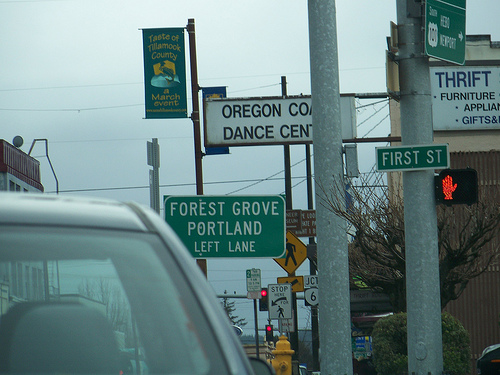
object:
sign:
[376, 144, 450, 173]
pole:
[396, 0, 444, 374]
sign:
[436, 170, 479, 203]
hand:
[443, 175, 457, 200]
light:
[261, 291, 267, 296]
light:
[266, 326, 271, 331]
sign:
[162, 194, 287, 260]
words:
[171, 201, 226, 216]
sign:
[207, 98, 311, 141]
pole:
[205, 136, 311, 149]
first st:
[381, 150, 443, 166]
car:
[0, 191, 248, 373]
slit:
[123, 202, 158, 234]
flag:
[143, 28, 187, 120]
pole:
[187, 17, 208, 264]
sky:
[0, 0, 499, 337]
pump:
[273, 336, 294, 374]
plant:
[373, 311, 404, 374]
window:
[9, 179, 15, 191]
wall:
[435, 149, 500, 374]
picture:
[0, 2, 498, 372]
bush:
[442, 312, 478, 374]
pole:
[280, 76, 299, 373]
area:
[2, 0, 498, 373]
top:
[0, 141, 44, 181]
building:
[0, 139, 45, 192]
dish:
[13, 135, 24, 147]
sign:
[247, 269, 261, 301]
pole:
[253, 298, 261, 364]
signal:
[259, 288, 268, 310]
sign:
[423, 1, 468, 65]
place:
[387, 35, 500, 374]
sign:
[269, 229, 310, 273]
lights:
[259, 286, 273, 341]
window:
[0, 225, 230, 373]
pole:
[306, 1, 354, 373]